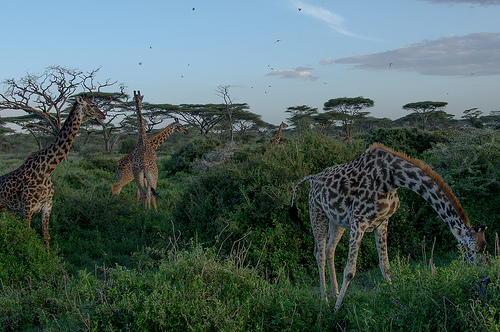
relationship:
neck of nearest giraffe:
[401, 151, 474, 225] [288, 139, 488, 314]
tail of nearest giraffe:
[286, 173, 309, 210] [288, 139, 488, 314]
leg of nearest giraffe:
[370, 230, 397, 286] [288, 139, 488, 314]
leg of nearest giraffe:
[332, 229, 363, 312] [288, 139, 488, 314]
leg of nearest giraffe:
[324, 225, 345, 292] [288, 139, 488, 314]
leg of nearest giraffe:
[309, 222, 330, 299] [288, 139, 488, 314]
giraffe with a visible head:
[1, 94, 108, 256] [74, 90, 108, 123]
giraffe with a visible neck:
[1, 94, 108, 256] [45, 122, 82, 167]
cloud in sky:
[319, 32, 499, 75] [1, 2, 499, 82]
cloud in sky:
[260, 64, 324, 92] [1, 2, 499, 82]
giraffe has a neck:
[1, 94, 108, 256] [45, 122, 82, 167]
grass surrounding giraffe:
[368, 258, 500, 330] [288, 139, 488, 314]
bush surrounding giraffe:
[1, 214, 89, 329] [1, 94, 108, 256]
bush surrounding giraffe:
[257, 129, 351, 276] [288, 139, 488, 314]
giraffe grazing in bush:
[288, 139, 488, 314] [368, 258, 500, 330]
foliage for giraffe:
[1, 214, 89, 329] [1, 94, 108, 256]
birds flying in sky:
[137, 6, 393, 98] [1, 2, 499, 82]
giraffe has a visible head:
[1, 94, 108, 256] [74, 90, 108, 123]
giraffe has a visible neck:
[1, 94, 108, 256] [45, 122, 82, 167]